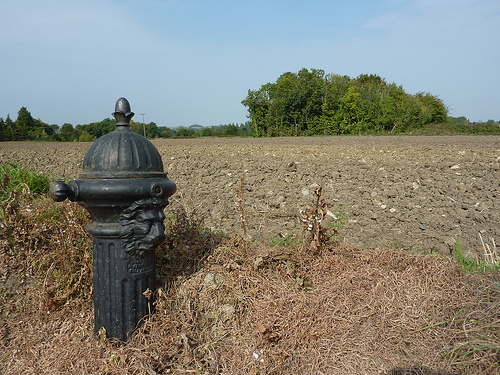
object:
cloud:
[7, 0, 495, 129]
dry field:
[2, 135, 498, 374]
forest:
[2, 62, 499, 142]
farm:
[1, 128, 493, 370]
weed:
[297, 185, 336, 257]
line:
[121, 132, 135, 171]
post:
[48, 97, 185, 351]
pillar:
[46, 97, 173, 340]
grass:
[0, 171, 498, 372]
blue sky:
[106, 13, 230, 98]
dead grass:
[9, 220, 489, 368]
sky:
[0, 0, 499, 128]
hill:
[245, 69, 463, 139]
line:
[110, 131, 124, 173]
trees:
[241, 84, 263, 136]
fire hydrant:
[36, 84, 190, 336]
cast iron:
[46, 96, 174, 340]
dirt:
[190, 139, 495, 255]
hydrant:
[46, 98, 175, 344]